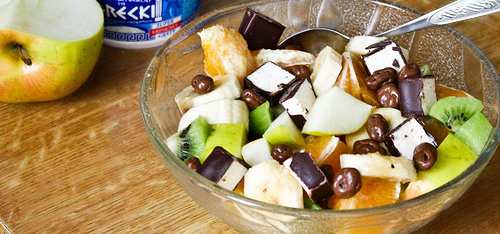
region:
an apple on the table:
[0, 0, 109, 110]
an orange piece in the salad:
[194, 20, 254, 82]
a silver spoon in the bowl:
[276, 0, 498, 52]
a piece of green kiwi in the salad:
[161, 112, 211, 164]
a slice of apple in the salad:
[298, 83, 374, 139]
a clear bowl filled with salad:
[136, 0, 498, 232]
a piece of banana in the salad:
[174, 95, 249, 132]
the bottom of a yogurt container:
[98, 0, 208, 52]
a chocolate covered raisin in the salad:
[190, 70, 215, 94]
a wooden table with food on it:
[1, 1, 499, 232]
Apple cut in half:
[6, 8, 105, 103]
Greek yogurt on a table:
[98, 3, 190, 53]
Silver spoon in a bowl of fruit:
[280, 0, 499, 52]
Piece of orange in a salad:
[195, 24, 249, 81]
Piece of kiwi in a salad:
[158, 121, 228, 180]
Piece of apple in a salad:
[301, 87, 385, 137]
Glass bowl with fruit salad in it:
[141, 23, 498, 225]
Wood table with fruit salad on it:
[25, 122, 164, 212]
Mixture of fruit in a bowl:
[184, 76, 378, 156]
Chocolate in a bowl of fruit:
[260, 137, 305, 162]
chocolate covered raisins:
[412, 141, 437, 170]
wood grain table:
[26, 120, 153, 224]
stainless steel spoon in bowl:
[270, 2, 498, 57]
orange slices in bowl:
[327, 177, 401, 208]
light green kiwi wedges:
[427, 95, 482, 134]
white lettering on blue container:
[105, 2, 156, 24]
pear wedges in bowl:
[299, 85, 375, 137]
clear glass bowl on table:
[138, 1, 498, 230]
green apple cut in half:
[1, 2, 103, 102]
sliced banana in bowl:
[173, 97, 249, 132]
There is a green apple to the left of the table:
[0, 0, 103, 103]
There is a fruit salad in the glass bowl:
[137, 8, 494, 233]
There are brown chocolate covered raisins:
[368, 63, 423, 112]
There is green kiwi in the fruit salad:
[161, 115, 203, 157]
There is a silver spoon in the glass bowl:
[279, 1, 498, 44]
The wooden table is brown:
[1, 0, 496, 230]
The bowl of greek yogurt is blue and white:
[100, 0, 200, 48]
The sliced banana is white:
[173, 70, 251, 130]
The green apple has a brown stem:
[8, 37, 38, 72]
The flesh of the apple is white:
[1, 2, 108, 44]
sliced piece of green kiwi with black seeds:
[429, 92, 480, 129]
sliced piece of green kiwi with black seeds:
[165, 118, 212, 160]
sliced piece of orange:
[196, 24, 251, 86]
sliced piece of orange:
[328, 167, 407, 212]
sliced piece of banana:
[243, 158, 302, 206]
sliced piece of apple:
[309, 92, 367, 135]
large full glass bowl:
[146, 1, 494, 227]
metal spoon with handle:
[275, 1, 496, 51]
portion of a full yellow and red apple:
[0, 2, 104, 102]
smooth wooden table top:
[2, 4, 498, 231]